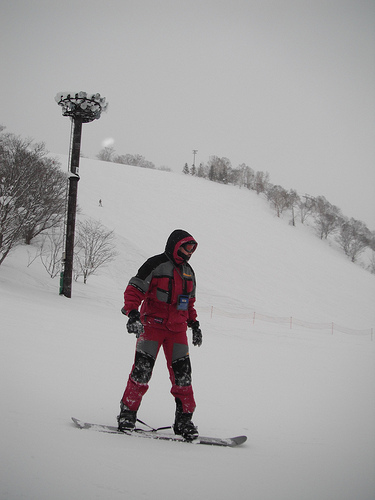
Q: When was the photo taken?
A: Daytime.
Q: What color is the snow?
A: White.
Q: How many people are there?
A: One.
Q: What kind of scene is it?
A: Outdoor.